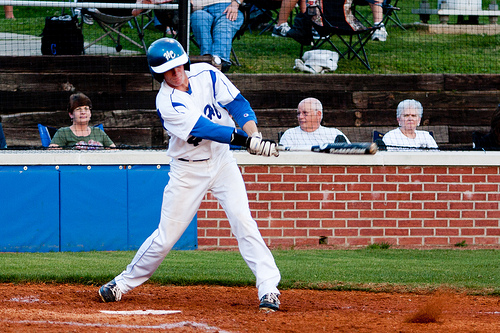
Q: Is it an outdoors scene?
A: Yes, it is outdoors.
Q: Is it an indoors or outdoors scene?
A: It is outdoors.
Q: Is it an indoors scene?
A: No, it is outdoors.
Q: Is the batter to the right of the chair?
A: Yes, the batter is to the right of the chair.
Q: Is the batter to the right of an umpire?
A: No, the batter is to the right of the chair.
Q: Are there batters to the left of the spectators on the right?
A: Yes, there is a batter to the left of the spectators.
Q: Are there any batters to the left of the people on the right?
A: Yes, there is a batter to the left of the spectators.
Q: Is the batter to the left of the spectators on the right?
A: Yes, the batter is to the left of the spectators.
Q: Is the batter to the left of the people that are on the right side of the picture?
A: Yes, the batter is to the left of the spectators.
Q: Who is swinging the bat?
A: The batter is swinging the bat.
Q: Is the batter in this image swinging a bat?
A: Yes, the batter is swinging a bat.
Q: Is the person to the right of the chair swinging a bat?
A: Yes, the batter is swinging a bat.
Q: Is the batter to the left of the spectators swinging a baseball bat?
A: No, the batter is swinging a bat.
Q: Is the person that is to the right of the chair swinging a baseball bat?
A: No, the batter is swinging a bat.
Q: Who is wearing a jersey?
A: The batter is wearing a jersey.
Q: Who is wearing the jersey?
A: The batter is wearing a jersey.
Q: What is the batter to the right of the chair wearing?
A: The batter is wearing a jersey.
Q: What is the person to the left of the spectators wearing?
A: The batter is wearing a jersey.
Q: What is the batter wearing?
A: The batter is wearing a jersey.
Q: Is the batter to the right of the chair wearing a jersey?
A: Yes, the batter is wearing a jersey.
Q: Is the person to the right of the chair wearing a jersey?
A: Yes, the batter is wearing a jersey.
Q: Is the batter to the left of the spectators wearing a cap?
A: No, the batter is wearing a jersey.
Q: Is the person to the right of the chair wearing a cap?
A: No, the batter is wearing a jersey.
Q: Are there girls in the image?
A: No, there are no girls.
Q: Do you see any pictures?
A: No, there are no pictures.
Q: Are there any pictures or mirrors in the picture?
A: No, there are no pictures or mirrors.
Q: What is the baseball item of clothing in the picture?
A: The clothing item is a uniform.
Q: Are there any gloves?
A: Yes, there are gloves.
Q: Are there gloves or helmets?
A: Yes, there are gloves.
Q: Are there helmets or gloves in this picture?
A: Yes, there are gloves.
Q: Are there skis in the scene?
A: No, there are no skis.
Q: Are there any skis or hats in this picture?
A: No, there are no skis or hats.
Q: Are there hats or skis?
A: No, there are no skis or hats.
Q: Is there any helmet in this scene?
A: Yes, there is a helmet.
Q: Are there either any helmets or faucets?
A: Yes, there is a helmet.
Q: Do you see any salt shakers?
A: No, there are no salt shakers.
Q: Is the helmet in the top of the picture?
A: Yes, the helmet is in the top of the image.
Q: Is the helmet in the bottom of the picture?
A: No, the helmet is in the top of the image.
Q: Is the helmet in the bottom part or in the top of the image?
A: The helmet is in the top of the image.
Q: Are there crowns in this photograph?
A: No, there are no crowns.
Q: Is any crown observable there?
A: No, there are no crowns.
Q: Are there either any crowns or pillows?
A: No, there are no crowns or pillows.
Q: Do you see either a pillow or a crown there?
A: No, there are no crowns or pillows.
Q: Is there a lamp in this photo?
A: No, there are no lamps.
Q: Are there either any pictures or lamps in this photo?
A: No, there are no lamps or pictures.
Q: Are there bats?
A: Yes, there is a bat.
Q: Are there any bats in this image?
A: Yes, there is a bat.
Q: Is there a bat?
A: Yes, there is a bat.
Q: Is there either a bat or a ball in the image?
A: Yes, there is a bat.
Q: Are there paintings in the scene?
A: No, there are no paintings.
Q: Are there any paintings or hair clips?
A: No, there are no paintings or hair clips.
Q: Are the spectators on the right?
A: Yes, the spectators are on the right of the image.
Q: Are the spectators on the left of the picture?
A: No, the spectators are on the right of the image.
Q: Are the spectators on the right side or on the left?
A: The spectators are on the right of the image.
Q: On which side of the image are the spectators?
A: The spectators are on the right of the image.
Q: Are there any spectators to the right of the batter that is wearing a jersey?
A: Yes, there are spectators to the right of the batter.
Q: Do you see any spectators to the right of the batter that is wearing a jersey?
A: Yes, there are spectators to the right of the batter.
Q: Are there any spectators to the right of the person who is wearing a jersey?
A: Yes, there are spectators to the right of the batter.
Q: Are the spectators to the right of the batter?
A: Yes, the spectators are to the right of the batter.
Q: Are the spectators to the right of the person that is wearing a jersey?
A: Yes, the spectators are to the right of the batter.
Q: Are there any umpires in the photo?
A: No, there are no umpires.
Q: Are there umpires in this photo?
A: No, there are no umpires.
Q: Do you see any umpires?
A: No, there are no umpires.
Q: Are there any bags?
A: Yes, there is a bag.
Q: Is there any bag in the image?
A: Yes, there is a bag.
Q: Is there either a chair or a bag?
A: Yes, there is a bag.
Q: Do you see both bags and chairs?
A: Yes, there are both a bag and a chair.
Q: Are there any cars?
A: No, there are no cars.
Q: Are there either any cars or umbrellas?
A: No, there are no cars or umbrellas.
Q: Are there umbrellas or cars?
A: No, there are no cars or umbrellas.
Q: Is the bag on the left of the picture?
A: Yes, the bag is on the left of the image.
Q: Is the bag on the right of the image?
A: No, the bag is on the left of the image.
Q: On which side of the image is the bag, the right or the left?
A: The bag is on the left of the image.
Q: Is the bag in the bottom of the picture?
A: No, the bag is in the top of the image.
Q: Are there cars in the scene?
A: No, there are no cars.